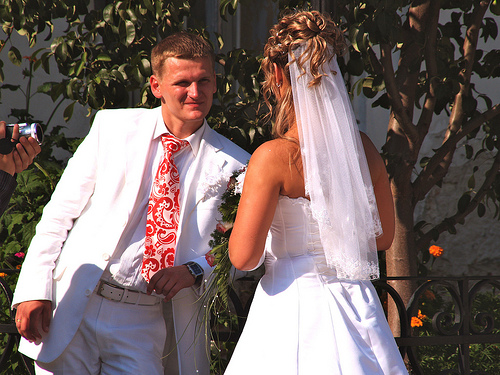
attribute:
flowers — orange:
[407, 241, 445, 335]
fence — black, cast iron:
[369, 270, 482, 372]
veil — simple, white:
[282, 40, 385, 281]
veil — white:
[291, 53, 374, 267]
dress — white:
[251, 191, 377, 356]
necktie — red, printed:
[144, 125, 190, 282]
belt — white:
[84, 275, 153, 319]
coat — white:
[70, 111, 217, 255]